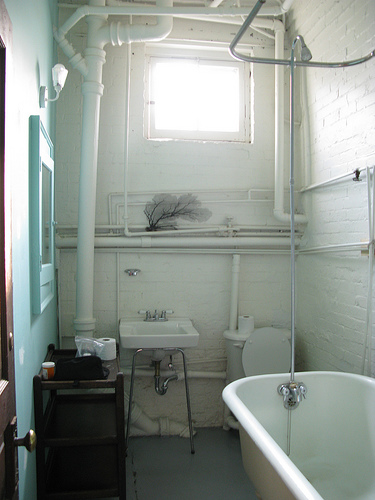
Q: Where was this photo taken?
A: Bathroom.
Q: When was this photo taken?
A: Daytime.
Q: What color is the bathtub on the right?
A: White.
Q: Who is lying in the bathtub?
A: No one.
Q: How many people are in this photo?
A: Zero.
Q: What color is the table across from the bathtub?
A: Brown.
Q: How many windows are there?
A: One.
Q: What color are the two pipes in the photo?
A: White.